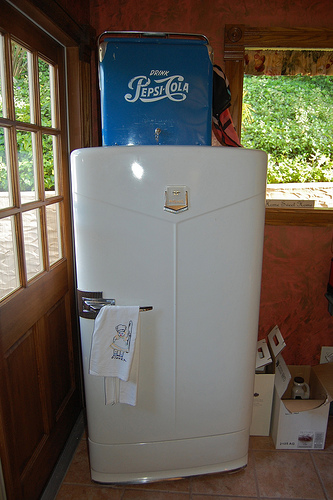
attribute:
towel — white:
[87, 301, 150, 409]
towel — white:
[88, 304, 141, 390]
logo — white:
[116, 65, 213, 133]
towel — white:
[81, 301, 164, 412]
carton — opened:
[274, 362, 332, 449]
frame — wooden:
[2, 1, 72, 320]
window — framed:
[1, 33, 65, 301]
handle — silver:
[82, 298, 150, 316]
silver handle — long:
[99, 29, 203, 37]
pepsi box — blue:
[97, 30, 214, 147]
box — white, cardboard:
[266, 327, 331, 449]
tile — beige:
[244, 442, 326, 496]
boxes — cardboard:
[279, 363, 328, 450]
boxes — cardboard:
[251, 342, 270, 439]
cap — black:
[291, 374, 308, 386]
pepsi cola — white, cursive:
[137, 73, 194, 104]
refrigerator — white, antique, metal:
[70, 145, 273, 480]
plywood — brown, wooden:
[21, 268, 76, 444]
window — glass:
[250, 67, 331, 196]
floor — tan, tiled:
[56, 394, 330, 498]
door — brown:
[3, 27, 75, 400]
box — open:
[273, 359, 331, 455]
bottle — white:
[279, 363, 310, 396]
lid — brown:
[295, 377, 302, 382]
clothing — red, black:
[212, 64, 242, 147]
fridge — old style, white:
[70, 144, 267, 483]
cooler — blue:
[96, 29, 212, 147]